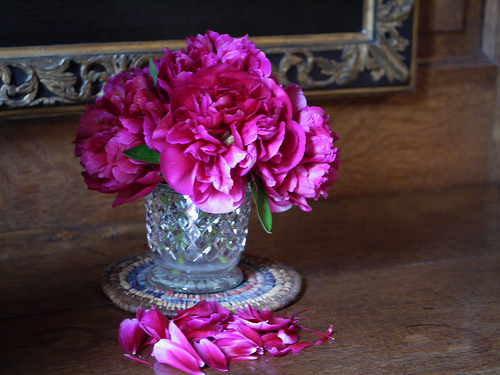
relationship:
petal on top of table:
[192, 338, 228, 371] [1, 66, 500, 374]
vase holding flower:
[145, 180, 250, 293] [73, 97, 165, 209]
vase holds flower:
[145, 180, 250, 293] [265, 105, 341, 213]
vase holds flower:
[145, 180, 250, 293] [172, 63, 260, 131]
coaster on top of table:
[102, 246, 302, 317] [1, 66, 500, 374]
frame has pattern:
[0, 0, 419, 118] [1, 60, 81, 105]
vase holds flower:
[145, 180, 250, 293] [73, 97, 165, 209]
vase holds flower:
[145, 180, 250, 293] [157, 29, 272, 94]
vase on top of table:
[145, 180, 250, 293] [1, 66, 500, 374]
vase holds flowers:
[145, 180, 250, 293] [73, 29, 343, 213]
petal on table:
[239, 312, 291, 332] [1, 66, 500, 374]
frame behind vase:
[0, 0, 419, 118] [145, 180, 250, 293]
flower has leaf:
[73, 97, 165, 209] [122, 143, 162, 165]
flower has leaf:
[265, 105, 341, 213] [250, 172, 272, 234]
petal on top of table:
[118, 318, 143, 357] [1, 66, 500, 374]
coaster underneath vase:
[102, 246, 302, 317] [145, 180, 250, 293]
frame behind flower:
[0, 0, 419, 118] [172, 63, 260, 131]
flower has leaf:
[157, 29, 272, 94] [149, 54, 159, 86]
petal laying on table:
[154, 338, 207, 374] [1, 66, 500, 374]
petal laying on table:
[139, 307, 169, 341] [1, 66, 500, 374]